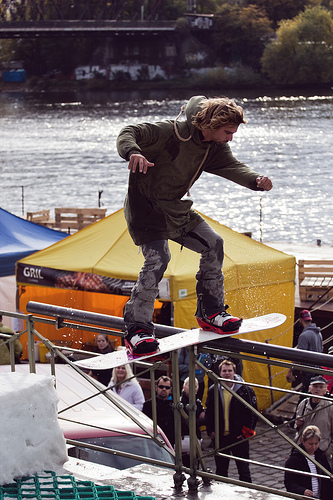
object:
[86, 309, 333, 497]
crowd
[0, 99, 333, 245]
water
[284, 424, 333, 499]
woman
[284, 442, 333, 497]
coat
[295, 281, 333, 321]
deck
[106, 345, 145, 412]
blonde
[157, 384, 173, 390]
shades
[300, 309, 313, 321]
hat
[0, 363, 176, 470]
vehicle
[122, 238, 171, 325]
leg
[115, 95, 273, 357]
man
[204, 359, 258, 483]
man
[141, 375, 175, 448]
man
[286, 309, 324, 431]
man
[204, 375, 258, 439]
jacket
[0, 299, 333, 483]
rail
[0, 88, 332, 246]
body water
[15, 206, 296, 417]
tent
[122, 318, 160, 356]
boots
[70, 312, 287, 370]
board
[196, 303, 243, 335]
snow boot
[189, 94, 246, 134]
giraffe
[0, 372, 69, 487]
snow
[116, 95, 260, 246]
hoodie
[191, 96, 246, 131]
hair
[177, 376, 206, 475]
person